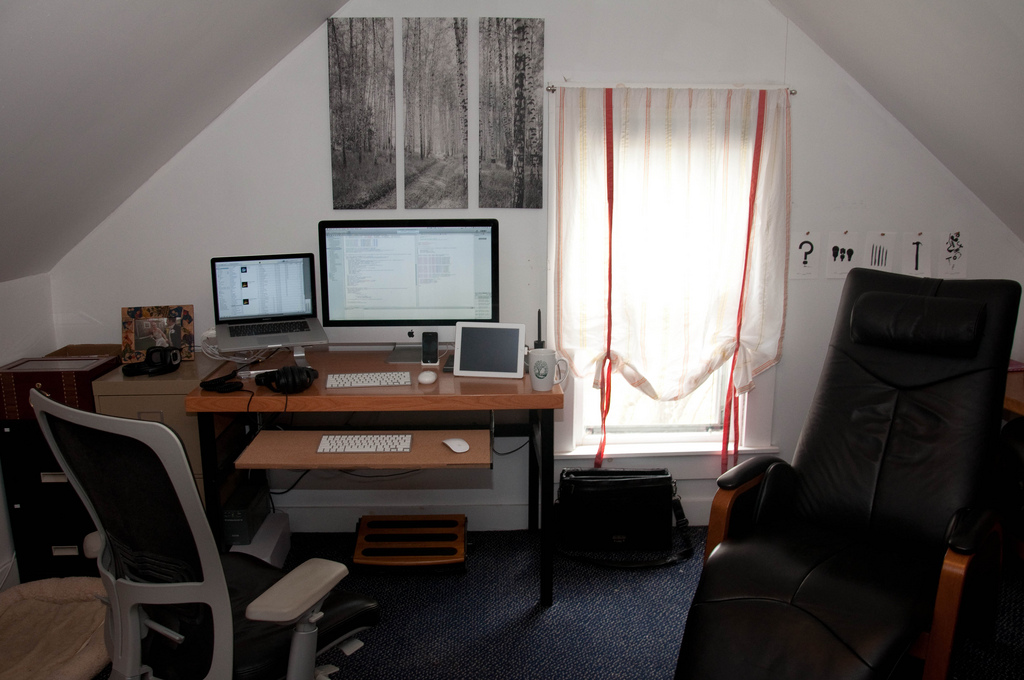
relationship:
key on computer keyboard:
[354, 437, 367, 448] [302, 416, 430, 465]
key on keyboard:
[361, 435, 375, 448] [313, 431, 413, 454]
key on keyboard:
[324, 435, 332, 449] [313, 429, 412, 455]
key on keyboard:
[351, 371, 364, 382] [322, 368, 415, 389]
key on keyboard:
[390, 369, 406, 377] [322, 368, 409, 388]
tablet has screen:
[454, 318, 525, 377] [464, 329, 514, 379]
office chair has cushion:
[24, 387, 375, 676] [215, 539, 283, 604]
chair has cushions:
[682, 268, 1022, 676] [761, 280, 986, 672]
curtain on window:
[543, 72, 801, 461] [550, 82, 781, 460]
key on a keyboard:
[374, 431, 391, 442] [316, 429, 414, 459]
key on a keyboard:
[327, 371, 344, 379] [322, 365, 415, 389]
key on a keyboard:
[377, 371, 390, 378] [317, 364, 410, 387]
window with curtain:
[539, 74, 798, 464] [555, 90, 791, 427]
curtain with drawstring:
[555, 90, 791, 427] [590, 80, 772, 448]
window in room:
[550, 82, 781, 460] [2, 6, 1022, 676]